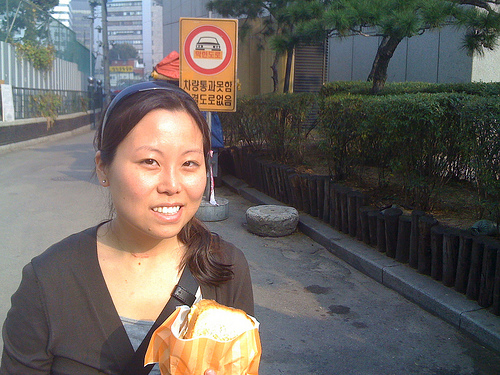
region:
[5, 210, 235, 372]
woman wearing a black shirt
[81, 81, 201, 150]
woman with black hair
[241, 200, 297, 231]
concrete boulder on the street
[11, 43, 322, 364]
this is a woman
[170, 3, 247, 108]
the sign is orange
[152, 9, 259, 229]
sign on a pole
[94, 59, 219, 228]
woman wearing a headband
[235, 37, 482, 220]
bushes on the side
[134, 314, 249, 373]
The sandwich is wrapped in striped paper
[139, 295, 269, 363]
The woman has not eaten the sandwich yet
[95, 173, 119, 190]
The woman has a earring in her hair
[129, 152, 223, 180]
The eyes of the woman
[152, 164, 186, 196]
The nose of the woman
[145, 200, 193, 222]
The mouth of the woman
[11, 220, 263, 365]
The woman is wearing black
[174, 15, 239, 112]
A tall orange sign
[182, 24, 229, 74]
A red circle on an orange sign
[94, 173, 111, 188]
An earring in a girl's ear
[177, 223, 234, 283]
A brown pony tail on a girl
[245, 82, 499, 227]
A green hedge near the street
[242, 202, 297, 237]
A stone base for a post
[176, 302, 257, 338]
A sandwich in a bag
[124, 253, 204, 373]
A black strap across a woman's chest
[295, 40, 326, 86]
Wooden shutter on a window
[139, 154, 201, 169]
Eyes in a girl's face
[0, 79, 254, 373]
A brown haired woman smiling.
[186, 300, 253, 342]
A sandwich in an orange wrap.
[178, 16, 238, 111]
Orange sign with red circle on it.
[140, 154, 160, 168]
A woman's right eye.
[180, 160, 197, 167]
A woman's left eye.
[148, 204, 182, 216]
A woman's white teeth.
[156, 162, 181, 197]
Nose of a woman.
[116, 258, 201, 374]
A black strap around a woman.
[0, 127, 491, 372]
Long paved drive.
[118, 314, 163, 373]
Grey shirt under a black one.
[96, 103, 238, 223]
face of the lady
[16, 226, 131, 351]
dark shirt on the lady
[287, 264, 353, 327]
shadow on the ground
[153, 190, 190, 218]
teeth of the lady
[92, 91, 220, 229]
the head of a woman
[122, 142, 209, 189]
the eyes of a woman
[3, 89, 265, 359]
a person walking on a sidewalk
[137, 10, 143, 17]
a window on a building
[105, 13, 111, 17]
a window on a building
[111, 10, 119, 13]
a window on a building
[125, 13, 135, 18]
a window on a building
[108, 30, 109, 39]
a window on a building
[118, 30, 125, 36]
a window on a building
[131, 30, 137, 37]
a window on a building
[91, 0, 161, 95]
a building in a city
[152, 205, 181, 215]
the teeth are white